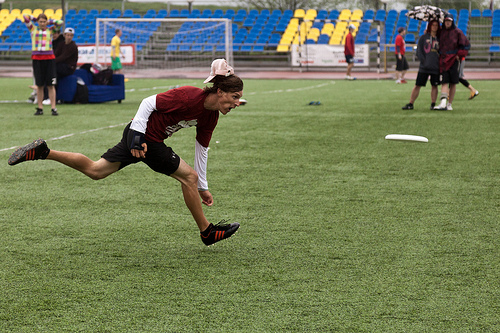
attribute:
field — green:
[2, 72, 500, 332]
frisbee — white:
[383, 127, 430, 148]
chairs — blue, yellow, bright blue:
[2, 7, 497, 51]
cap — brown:
[211, 77, 243, 95]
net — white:
[103, 24, 222, 75]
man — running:
[8, 73, 248, 254]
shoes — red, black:
[6, 138, 241, 255]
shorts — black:
[109, 125, 183, 173]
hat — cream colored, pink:
[202, 55, 234, 79]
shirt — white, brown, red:
[130, 87, 219, 194]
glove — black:
[124, 127, 145, 147]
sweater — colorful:
[25, 20, 59, 57]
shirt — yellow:
[106, 34, 122, 57]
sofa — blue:
[57, 63, 122, 103]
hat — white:
[62, 26, 71, 35]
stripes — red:
[25, 148, 224, 242]